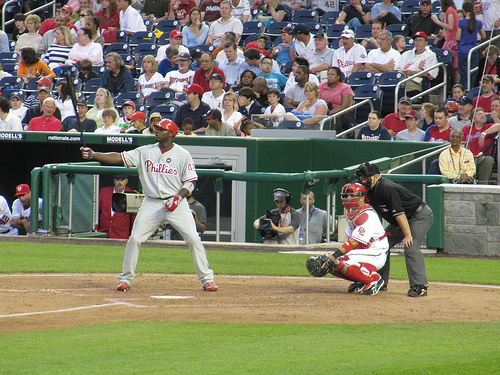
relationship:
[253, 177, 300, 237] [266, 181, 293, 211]
man wears headphones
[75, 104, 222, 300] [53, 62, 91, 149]
player holds bat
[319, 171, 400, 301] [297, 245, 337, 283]
catcher has mitt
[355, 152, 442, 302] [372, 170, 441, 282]
umpire wears black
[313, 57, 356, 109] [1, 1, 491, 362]
fan in stadium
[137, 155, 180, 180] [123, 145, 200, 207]
phillies logo on shirt says phillies